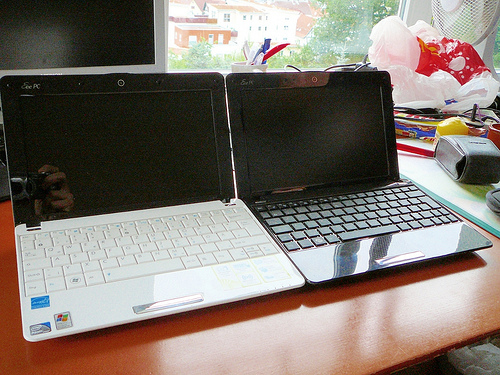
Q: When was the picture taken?
A: Daytime.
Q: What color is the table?
A: Brown.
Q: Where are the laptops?
A: On the table.